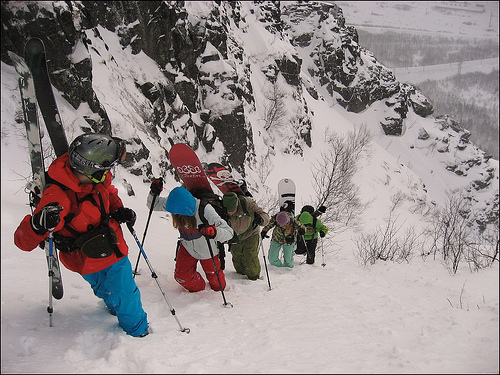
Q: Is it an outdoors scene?
A: Yes, it is outdoors.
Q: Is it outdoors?
A: Yes, it is outdoors.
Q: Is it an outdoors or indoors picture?
A: It is outdoors.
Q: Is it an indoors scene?
A: No, it is outdoors.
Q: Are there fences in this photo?
A: No, there are no fences.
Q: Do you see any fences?
A: No, there are no fences.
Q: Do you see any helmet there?
A: Yes, there is a helmet.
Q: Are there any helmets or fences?
A: Yes, there is a helmet.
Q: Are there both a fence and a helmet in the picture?
A: No, there is a helmet but no fences.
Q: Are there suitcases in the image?
A: No, there are no suitcases.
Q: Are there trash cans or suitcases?
A: No, there are no suitcases or trash cans.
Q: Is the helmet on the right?
A: No, the helmet is on the left of the image.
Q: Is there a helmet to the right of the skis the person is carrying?
A: Yes, there is a helmet to the right of the skis.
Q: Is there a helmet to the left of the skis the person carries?
A: No, the helmet is to the right of the skis.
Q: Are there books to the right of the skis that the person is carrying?
A: No, there is a helmet to the right of the skis.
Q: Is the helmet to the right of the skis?
A: Yes, the helmet is to the right of the skis.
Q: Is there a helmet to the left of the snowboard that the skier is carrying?
A: Yes, there is a helmet to the left of the snowboard.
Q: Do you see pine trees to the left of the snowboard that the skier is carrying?
A: No, there is a helmet to the left of the snowboard.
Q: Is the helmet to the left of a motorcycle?
A: No, the helmet is to the left of the snow board.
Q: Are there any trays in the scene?
A: No, there are no trays.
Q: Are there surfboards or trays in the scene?
A: No, there are no trays or surfboards.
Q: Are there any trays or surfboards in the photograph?
A: No, there are no trays or surfboards.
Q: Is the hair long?
A: Yes, the hair is long.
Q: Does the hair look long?
A: Yes, the hair is long.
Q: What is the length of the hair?
A: The hair is long.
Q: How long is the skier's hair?
A: The hair is long.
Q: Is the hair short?
A: No, the hair is long.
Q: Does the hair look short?
A: No, the hair is long.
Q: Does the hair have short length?
A: No, the hair is long.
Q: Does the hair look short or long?
A: The hair is long.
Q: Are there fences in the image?
A: No, there are no fences.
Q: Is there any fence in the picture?
A: No, there are no fences.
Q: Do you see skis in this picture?
A: Yes, there are skis.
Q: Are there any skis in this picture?
A: Yes, there are skis.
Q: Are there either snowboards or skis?
A: Yes, there are skis.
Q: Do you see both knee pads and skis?
A: No, there are skis but no knee pads.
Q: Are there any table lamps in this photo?
A: No, there are no table lamps.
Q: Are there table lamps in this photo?
A: No, there are no table lamps.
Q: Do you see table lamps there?
A: No, there are no table lamps.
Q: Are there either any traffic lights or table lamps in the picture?
A: No, there are no table lamps or traffic lights.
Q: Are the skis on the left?
A: Yes, the skis are on the left of the image.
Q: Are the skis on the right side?
A: No, the skis are on the left of the image.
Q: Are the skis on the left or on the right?
A: The skis are on the left of the image.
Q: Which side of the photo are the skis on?
A: The skis are on the left of the image.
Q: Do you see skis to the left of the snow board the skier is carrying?
A: Yes, there are skis to the left of the snowboard.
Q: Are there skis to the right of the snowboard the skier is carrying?
A: No, the skis are to the left of the snowboard.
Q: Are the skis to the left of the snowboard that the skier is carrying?
A: Yes, the skis are to the left of the snowboard.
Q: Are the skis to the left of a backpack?
A: No, the skis are to the left of the snowboard.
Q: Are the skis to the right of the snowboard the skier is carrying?
A: No, the skis are to the left of the snow board.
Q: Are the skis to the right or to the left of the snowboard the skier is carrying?
A: The skis are to the left of the snowboard.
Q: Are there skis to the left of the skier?
A: Yes, there are skis to the left of the skier.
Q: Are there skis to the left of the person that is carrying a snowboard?
A: Yes, there are skis to the left of the skier.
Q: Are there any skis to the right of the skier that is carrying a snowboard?
A: No, the skis are to the left of the skier.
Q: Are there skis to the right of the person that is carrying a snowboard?
A: No, the skis are to the left of the skier.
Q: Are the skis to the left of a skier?
A: Yes, the skis are to the left of a skier.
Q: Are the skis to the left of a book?
A: No, the skis are to the left of a skier.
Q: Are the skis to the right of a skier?
A: No, the skis are to the left of a skier.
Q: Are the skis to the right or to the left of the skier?
A: The skis are to the left of the skier.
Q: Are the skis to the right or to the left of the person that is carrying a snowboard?
A: The skis are to the left of the skier.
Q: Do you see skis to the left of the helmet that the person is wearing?
A: Yes, there are skis to the left of the helmet.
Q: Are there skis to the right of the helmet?
A: No, the skis are to the left of the helmet.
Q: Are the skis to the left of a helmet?
A: Yes, the skis are to the left of a helmet.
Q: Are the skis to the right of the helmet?
A: No, the skis are to the left of the helmet.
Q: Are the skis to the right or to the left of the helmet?
A: The skis are to the left of the helmet.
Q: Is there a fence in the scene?
A: No, there are no fences.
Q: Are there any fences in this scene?
A: No, there are no fences.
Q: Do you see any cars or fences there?
A: No, there are no fences or cars.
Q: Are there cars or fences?
A: No, there are no fences or cars.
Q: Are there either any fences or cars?
A: No, there are no fences or cars.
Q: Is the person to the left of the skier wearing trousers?
A: Yes, the person is wearing trousers.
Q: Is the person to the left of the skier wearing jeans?
A: No, the person is wearing trousers.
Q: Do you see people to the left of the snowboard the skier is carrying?
A: Yes, there is a person to the left of the snowboard.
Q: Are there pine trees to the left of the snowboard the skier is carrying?
A: No, there is a person to the left of the snowboard.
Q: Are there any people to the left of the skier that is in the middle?
A: Yes, there is a person to the left of the skier.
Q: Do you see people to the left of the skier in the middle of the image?
A: Yes, there is a person to the left of the skier.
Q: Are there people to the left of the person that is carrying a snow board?
A: Yes, there is a person to the left of the skier.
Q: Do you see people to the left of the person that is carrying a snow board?
A: Yes, there is a person to the left of the skier.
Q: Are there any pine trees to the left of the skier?
A: No, there is a person to the left of the skier.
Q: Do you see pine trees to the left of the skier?
A: No, there is a person to the left of the skier.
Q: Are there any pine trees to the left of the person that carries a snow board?
A: No, there is a person to the left of the skier.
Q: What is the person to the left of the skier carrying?
A: The person is carrying skis.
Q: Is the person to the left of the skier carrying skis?
A: Yes, the person is carrying skis.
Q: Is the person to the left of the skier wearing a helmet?
A: Yes, the person is wearing a helmet.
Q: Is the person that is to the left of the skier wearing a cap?
A: No, the person is wearing a helmet.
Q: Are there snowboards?
A: Yes, there is a snowboard.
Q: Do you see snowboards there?
A: Yes, there is a snowboard.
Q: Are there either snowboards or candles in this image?
A: Yes, there is a snowboard.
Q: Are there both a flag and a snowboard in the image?
A: No, there is a snowboard but no flags.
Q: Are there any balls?
A: No, there are no balls.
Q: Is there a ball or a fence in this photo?
A: No, there are no balls or fences.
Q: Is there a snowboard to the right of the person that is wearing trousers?
A: Yes, there is a snowboard to the right of the person.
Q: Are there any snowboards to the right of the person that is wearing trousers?
A: Yes, there is a snowboard to the right of the person.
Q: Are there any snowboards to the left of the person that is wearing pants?
A: No, the snowboard is to the right of the person.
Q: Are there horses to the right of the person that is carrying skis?
A: No, there is a snowboard to the right of the person.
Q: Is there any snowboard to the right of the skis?
A: Yes, there is a snowboard to the right of the skis.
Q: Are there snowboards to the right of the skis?
A: Yes, there is a snowboard to the right of the skis.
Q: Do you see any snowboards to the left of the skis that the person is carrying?
A: No, the snowboard is to the right of the skis.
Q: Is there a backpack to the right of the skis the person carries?
A: No, there is a snowboard to the right of the skis.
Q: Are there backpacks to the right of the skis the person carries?
A: No, there is a snowboard to the right of the skis.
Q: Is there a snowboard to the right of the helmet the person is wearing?
A: Yes, there is a snowboard to the right of the helmet.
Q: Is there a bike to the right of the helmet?
A: No, there is a snowboard to the right of the helmet.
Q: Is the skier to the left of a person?
A: Yes, the skier is to the left of a person.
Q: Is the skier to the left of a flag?
A: No, the skier is to the left of a person.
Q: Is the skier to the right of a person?
A: No, the skier is to the left of a person.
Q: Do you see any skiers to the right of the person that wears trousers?
A: Yes, there is a skier to the right of the person.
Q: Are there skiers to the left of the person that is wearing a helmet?
A: No, the skier is to the right of the person.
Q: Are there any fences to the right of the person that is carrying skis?
A: No, there is a skier to the right of the person.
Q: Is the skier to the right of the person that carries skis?
A: Yes, the skier is to the right of the person.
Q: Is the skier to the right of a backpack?
A: No, the skier is to the right of the person.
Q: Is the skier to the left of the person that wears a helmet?
A: No, the skier is to the right of the person.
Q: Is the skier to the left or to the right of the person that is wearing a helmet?
A: The skier is to the right of the person.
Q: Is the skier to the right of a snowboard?
A: No, the skier is to the left of a snowboard.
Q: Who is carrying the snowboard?
A: The skier is carrying the snowboard.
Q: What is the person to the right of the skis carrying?
A: The skier is carrying a snowboard.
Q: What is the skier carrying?
A: The skier is carrying a snowboard.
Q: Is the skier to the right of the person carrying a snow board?
A: Yes, the skier is carrying a snow board.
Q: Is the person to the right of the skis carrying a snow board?
A: Yes, the skier is carrying a snow board.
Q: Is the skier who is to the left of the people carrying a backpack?
A: No, the skier is carrying a snow board.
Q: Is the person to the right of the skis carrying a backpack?
A: No, the skier is carrying a snow board.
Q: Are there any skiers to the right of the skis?
A: Yes, there is a skier to the right of the skis.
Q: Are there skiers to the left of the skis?
A: No, the skier is to the right of the skis.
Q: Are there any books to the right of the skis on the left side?
A: No, there is a skier to the right of the skis.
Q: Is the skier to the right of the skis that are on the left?
A: Yes, the skier is to the right of the skis.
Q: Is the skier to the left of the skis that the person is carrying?
A: No, the skier is to the right of the skis.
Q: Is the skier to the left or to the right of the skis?
A: The skier is to the right of the skis.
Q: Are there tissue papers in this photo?
A: No, there are no tissue papers.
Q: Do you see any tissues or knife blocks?
A: No, there are no tissues or knife blocks.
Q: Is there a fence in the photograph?
A: No, there are no fences.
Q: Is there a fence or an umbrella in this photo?
A: No, there are no fences or umbrellas.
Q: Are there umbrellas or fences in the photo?
A: No, there are no fences or umbrellas.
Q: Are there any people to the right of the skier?
A: Yes, there are people to the right of the skier.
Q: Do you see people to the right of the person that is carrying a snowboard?
A: Yes, there are people to the right of the skier.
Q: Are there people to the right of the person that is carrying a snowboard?
A: Yes, there are people to the right of the skier.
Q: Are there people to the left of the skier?
A: No, the people are to the right of the skier.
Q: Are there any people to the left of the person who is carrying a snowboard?
A: No, the people are to the right of the skier.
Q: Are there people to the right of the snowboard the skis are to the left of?
A: Yes, there are people to the right of the snowboard.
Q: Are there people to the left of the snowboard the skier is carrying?
A: No, the people are to the right of the snowboard.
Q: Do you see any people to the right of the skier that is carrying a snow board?
A: Yes, there is a person to the right of the skier.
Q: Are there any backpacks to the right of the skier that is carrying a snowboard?
A: No, there is a person to the right of the skier.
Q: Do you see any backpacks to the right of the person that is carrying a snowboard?
A: No, there is a person to the right of the skier.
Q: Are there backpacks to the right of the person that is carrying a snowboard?
A: No, there is a person to the right of the skier.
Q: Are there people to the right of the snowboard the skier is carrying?
A: Yes, there is a person to the right of the snowboard.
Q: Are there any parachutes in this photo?
A: No, there are no parachutes.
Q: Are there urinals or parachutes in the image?
A: No, there are no parachutes or urinals.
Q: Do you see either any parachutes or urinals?
A: No, there are no parachutes or urinals.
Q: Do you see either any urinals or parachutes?
A: No, there are no parachutes or urinals.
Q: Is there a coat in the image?
A: Yes, there is a coat.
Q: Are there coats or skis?
A: Yes, there is a coat.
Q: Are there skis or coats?
A: Yes, there is a coat.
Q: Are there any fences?
A: No, there are no fences.